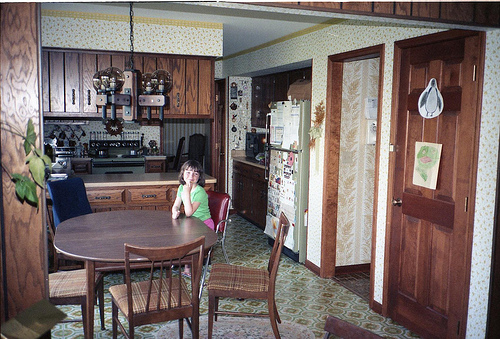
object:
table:
[41, 197, 223, 337]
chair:
[200, 208, 297, 338]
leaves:
[20, 118, 41, 157]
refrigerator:
[261, 96, 313, 265]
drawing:
[417, 76, 446, 120]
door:
[368, 26, 492, 339]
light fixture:
[90, 3, 177, 135]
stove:
[87, 135, 149, 180]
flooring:
[46, 203, 425, 339]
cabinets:
[193, 53, 216, 118]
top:
[172, 184, 212, 221]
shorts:
[200, 215, 216, 234]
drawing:
[411, 138, 444, 191]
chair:
[197, 184, 239, 266]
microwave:
[240, 127, 268, 160]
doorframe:
[318, 40, 386, 296]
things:
[306, 99, 324, 152]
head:
[172, 157, 204, 190]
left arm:
[181, 182, 205, 218]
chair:
[41, 167, 92, 231]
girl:
[163, 154, 220, 232]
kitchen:
[0, 0, 500, 335]